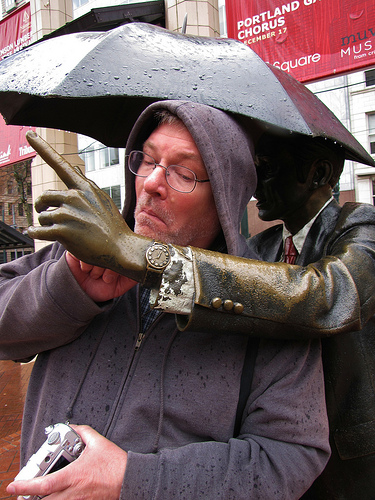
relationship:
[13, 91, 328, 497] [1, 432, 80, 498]
man holds camera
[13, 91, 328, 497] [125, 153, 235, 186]
man has glasses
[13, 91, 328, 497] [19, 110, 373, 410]
man near statue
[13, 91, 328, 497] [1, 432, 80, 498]
man has camera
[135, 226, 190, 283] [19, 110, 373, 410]
watch on statue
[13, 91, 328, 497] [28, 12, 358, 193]
man under umbrella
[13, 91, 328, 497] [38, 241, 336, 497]
man wears sweatshirt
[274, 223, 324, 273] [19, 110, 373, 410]
tie on statue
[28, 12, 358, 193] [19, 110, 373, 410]
umbrella on statue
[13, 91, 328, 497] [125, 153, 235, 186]
man wears glasses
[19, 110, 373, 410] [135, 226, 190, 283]
statue wears watch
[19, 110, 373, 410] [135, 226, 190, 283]
statue has watch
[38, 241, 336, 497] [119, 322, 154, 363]
sweatshirt has zipper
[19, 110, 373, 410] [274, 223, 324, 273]
statue has tie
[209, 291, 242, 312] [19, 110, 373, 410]
buttons on statue